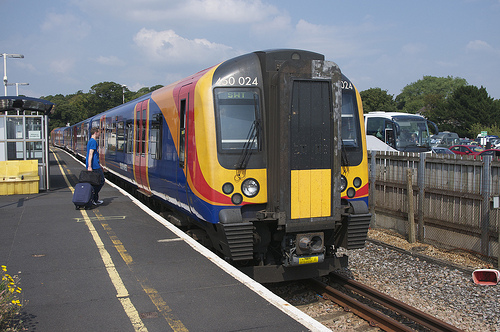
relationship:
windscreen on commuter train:
[212, 84, 357, 175] [50, 47, 375, 285]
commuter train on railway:
[50, 47, 375, 285] [161, 226, 471, 322]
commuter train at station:
[50, 47, 375, 285] [5, 25, 387, 330]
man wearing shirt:
[84, 124, 104, 207] [84, 138, 99, 165]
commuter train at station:
[50, 47, 375, 285] [0, 50, 334, 330]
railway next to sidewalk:
[310, 272, 466, 332] [56, 151, 230, 317]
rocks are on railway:
[345, 238, 500, 330] [310, 272, 466, 332]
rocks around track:
[378, 243, 447, 317] [156, 189, 494, 329]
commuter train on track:
[50, 47, 375, 285] [331, 283, 451, 330]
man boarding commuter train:
[85, 126, 106, 207] [50, 47, 375, 285]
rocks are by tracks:
[345, 238, 500, 330] [320, 258, 470, 330]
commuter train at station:
[50, 47, 375, 285] [2, 138, 489, 325]